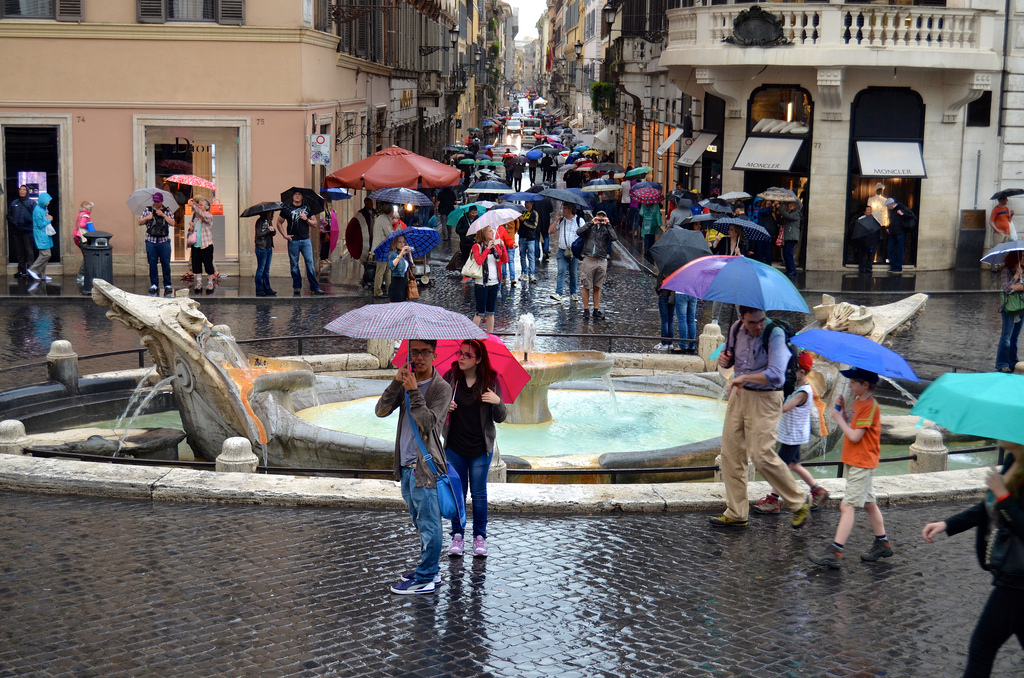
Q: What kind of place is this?
A: It is a street.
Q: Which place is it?
A: It is a street.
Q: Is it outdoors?
A: Yes, it is outdoors.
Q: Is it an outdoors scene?
A: Yes, it is outdoors.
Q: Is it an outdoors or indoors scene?
A: It is outdoors.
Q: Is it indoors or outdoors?
A: It is outdoors.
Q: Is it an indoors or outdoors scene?
A: It is outdoors.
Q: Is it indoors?
A: No, it is outdoors.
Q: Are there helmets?
A: No, there are no helmets.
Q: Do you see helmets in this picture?
A: No, there are no helmets.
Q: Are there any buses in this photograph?
A: No, there are no buses.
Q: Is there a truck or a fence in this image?
A: No, there are no fences or trucks.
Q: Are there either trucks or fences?
A: No, there are no fences or trucks.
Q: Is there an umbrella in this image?
A: Yes, there is an umbrella.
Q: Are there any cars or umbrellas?
A: Yes, there is an umbrella.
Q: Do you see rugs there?
A: No, there are no rugs.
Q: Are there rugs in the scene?
A: No, there are no rugs.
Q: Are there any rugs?
A: No, there are no rugs.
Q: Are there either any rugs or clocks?
A: No, there are no rugs or clocks.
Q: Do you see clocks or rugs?
A: No, there are no rugs or clocks.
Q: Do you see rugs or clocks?
A: No, there are no rugs or clocks.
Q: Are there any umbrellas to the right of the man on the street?
A: Yes, there is an umbrella to the right of the man.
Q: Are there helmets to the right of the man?
A: No, there is an umbrella to the right of the man.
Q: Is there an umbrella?
A: Yes, there is an umbrella.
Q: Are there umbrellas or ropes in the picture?
A: Yes, there is an umbrella.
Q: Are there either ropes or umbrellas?
A: Yes, there is an umbrella.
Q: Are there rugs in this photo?
A: No, there are no rugs.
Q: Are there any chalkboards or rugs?
A: No, there are no rugs or chalkboards.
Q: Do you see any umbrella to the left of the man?
A: Yes, there is an umbrella to the left of the man.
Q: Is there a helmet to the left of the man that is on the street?
A: No, there is an umbrella to the left of the man.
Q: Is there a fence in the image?
A: No, there are no fences.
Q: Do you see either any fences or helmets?
A: No, there are no fences or helmets.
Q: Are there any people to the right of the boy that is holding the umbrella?
A: Yes, there is a person to the right of the boy.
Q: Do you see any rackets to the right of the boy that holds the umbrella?
A: No, there is a person to the right of the boy.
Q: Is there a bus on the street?
A: No, there is a person on the street.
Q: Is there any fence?
A: No, there are no fences.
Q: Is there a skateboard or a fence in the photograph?
A: No, there are no fences or skateboards.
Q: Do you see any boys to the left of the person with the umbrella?
A: Yes, there is a boy to the left of the person.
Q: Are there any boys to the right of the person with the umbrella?
A: No, the boy is to the left of the person.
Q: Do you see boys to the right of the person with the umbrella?
A: No, the boy is to the left of the person.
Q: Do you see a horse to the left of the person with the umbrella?
A: No, there is a boy to the left of the person.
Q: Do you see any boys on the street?
A: Yes, there is a boy on the street.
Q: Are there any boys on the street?
A: Yes, there is a boy on the street.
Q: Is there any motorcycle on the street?
A: No, there is a boy on the street.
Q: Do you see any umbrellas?
A: Yes, there is an umbrella.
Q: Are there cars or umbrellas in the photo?
A: Yes, there is an umbrella.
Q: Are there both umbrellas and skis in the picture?
A: No, there is an umbrella but no skis.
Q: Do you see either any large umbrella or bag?
A: Yes, there is a large umbrella.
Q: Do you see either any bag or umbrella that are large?
A: Yes, the umbrella is large.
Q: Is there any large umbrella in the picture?
A: Yes, there is a large umbrella.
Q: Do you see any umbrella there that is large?
A: Yes, there is an umbrella that is large.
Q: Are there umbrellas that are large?
A: Yes, there is an umbrella that is large.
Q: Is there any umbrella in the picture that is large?
A: Yes, there is an umbrella that is large.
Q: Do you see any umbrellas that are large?
A: Yes, there is an umbrella that is large.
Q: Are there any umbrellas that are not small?
A: Yes, there is a large umbrella.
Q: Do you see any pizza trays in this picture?
A: No, there are no pizza trays.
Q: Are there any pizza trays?
A: No, there are no pizza trays.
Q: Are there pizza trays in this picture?
A: No, there are no pizza trays.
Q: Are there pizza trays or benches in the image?
A: No, there are no pizza trays or benches.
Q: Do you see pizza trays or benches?
A: No, there are no pizza trays or benches.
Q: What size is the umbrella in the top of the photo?
A: The umbrella is large.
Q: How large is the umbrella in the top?
A: The umbrella is large.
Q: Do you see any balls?
A: No, there are no balls.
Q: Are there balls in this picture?
A: No, there are no balls.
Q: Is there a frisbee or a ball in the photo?
A: No, there are no balls or frisbees.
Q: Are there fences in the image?
A: No, there are no fences.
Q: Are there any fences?
A: No, there are no fences.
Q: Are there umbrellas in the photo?
A: Yes, there is an umbrella.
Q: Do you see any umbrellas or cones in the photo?
A: Yes, there is an umbrella.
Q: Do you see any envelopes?
A: No, there are no envelopes.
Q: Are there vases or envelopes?
A: No, there are no envelopes or vases.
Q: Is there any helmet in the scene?
A: No, there are no helmets.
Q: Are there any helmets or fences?
A: No, there are no helmets or fences.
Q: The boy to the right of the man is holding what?
A: The boy is holding the umbrella.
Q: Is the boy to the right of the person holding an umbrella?
A: Yes, the boy is holding an umbrella.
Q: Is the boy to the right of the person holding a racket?
A: No, the boy is holding an umbrella.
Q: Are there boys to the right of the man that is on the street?
A: Yes, there is a boy to the right of the man.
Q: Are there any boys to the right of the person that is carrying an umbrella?
A: Yes, there is a boy to the right of the man.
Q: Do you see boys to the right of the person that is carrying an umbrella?
A: Yes, there is a boy to the right of the man.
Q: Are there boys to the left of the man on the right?
A: No, the boy is to the right of the man.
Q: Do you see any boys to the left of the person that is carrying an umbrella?
A: No, the boy is to the right of the man.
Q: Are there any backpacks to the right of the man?
A: No, there is a boy to the right of the man.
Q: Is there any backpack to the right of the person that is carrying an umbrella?
A: No, there is a boy to the right of the man.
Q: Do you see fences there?
A: No, there are no fences.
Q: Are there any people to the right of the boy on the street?
A: Yes, there is a person to the right of the boy.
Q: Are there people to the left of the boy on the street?
A: No, the person is to the right of the boy.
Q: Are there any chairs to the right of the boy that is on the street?
A: No, there is a person to the right of the boy.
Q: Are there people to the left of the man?
A: Yes, there is a person to the left of the man.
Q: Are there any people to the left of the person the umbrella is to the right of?
A: Yes, there is a person to the left of the man.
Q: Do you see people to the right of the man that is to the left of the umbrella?
A: No, the person is to the left of the man.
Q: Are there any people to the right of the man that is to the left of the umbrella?
A: No, the person is to the left of the man.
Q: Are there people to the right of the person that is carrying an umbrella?
A: No, the person is to the left of the man.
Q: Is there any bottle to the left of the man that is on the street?
A: No, there is a person to the left of the man.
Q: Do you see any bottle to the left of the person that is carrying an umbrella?
A: No, there is a person to the left of the man.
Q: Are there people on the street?
A: Yes, there is a person on the street.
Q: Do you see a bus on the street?
A: No, there is a person on the street.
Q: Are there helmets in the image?
A: No, there are no helmets.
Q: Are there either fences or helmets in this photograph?
A: No, there are no helmets or fences.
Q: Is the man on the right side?
A: Yes, the man is on the right of the image.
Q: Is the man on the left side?
A: No, the man is on the right of the image.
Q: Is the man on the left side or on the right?
A: The man is on the right of the image.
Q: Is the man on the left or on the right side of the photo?
A: The man is on the right of the image.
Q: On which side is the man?
A: The man is on the right of the image.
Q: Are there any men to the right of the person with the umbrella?
A: Yes, there is a man to the right of the person.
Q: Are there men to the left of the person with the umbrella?
A: No, the man is to the right of the person.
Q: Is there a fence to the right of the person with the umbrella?
A: No, there is a man to the right of the person.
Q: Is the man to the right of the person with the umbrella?
A: Yes, the man is to the right of the person.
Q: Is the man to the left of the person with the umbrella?
A: No, the man is to the right of the person.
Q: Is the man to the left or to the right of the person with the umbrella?
A: The man is to the right of the person.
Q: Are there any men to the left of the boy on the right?
A: Yes, there is a man to the left of the boy.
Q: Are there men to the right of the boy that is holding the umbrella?
A: No, the man is to the left of the boy.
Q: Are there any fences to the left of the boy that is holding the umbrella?
A: No, there is a man to the left of the boy.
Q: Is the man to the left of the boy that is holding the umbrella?
A: Yes, the man is to the left of the boy.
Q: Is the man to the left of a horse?
A: No, the man is to the left of the boy.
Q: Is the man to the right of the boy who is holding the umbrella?
A: No, the man is to the left of the boy.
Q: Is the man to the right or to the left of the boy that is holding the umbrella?
A: The man is to the left of the boy.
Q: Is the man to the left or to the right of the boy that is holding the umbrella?
A: The man is to the left of the boy.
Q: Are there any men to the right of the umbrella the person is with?
A: Yes, there is a man to the right of the umbrella.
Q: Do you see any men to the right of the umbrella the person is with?
A: Yes, there is a man to the right of the umbrella.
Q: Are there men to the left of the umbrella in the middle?
A: No, the man is to the right of the umbrella.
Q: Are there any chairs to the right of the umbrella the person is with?
A: No, there is a man to the right of the umbrella.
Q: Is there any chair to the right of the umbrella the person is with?
A: No, there is a man to the right of the umbrella.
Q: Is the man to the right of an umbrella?
A: Yes, the man is to the right of an umbrella.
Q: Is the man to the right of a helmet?
A: No, the man is to the right of an umbrella.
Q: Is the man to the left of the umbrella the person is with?
A: No, the man is to the right of the umbrella.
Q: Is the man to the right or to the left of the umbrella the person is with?
A: The man is to the right of the umbrella.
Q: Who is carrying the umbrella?
A: The man is carrying the umbrella.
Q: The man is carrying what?
A: The man is carrying an umbrella.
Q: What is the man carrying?
A: The man is carrying an umbrella.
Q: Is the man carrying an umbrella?
A: Yes, the man is carrying an umbrella.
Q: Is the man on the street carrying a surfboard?
A: No, the man is carrying an umbrella.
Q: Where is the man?
A: The man is on the street.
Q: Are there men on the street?
A: Yes, there is a man on the street.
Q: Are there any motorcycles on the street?
A: No, there is a man on the street.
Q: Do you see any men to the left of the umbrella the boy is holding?
A: Yes, there is a man to the left of the umbrella.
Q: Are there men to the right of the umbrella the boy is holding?
A: No, the man is to the left of the umbrella.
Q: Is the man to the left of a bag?
A: No, the man is to the left of the umbrella.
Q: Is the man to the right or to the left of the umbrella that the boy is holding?
A: The man is to the left of the umbrella.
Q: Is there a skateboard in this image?
A: No, there are no skateboards.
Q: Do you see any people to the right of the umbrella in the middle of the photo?
A: Yes, there is a person to the right of the umbrella.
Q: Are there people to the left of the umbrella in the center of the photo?
A: No, the person is to the right of the umbrella.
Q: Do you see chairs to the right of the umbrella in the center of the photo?
A: No, there is a person to the right of the umbrella.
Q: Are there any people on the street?
A: Yes, there is a person on the street.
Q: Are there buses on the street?
A: No, there is a person on the street.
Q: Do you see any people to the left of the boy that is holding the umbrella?
A: Yes, there is a person to the left of the boy.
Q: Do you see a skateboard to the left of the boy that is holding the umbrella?
A: No, there is a person to the left of the boy.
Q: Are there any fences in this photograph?
A: No, there are no fences.